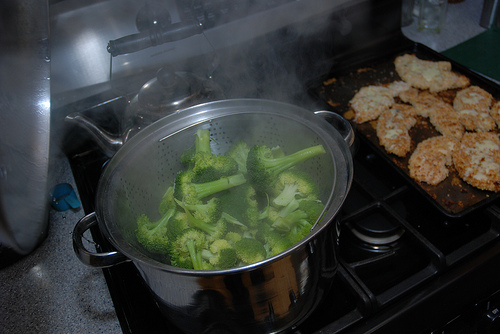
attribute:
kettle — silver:
[64, 53, 223, 155]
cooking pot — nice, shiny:
[72, 103, 359, 329]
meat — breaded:
[375, 101, 419, 158]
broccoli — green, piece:
[248, 139, 325, 184]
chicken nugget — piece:
[380, 94, 422, 176]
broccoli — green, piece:
[174, 160, 242, 214]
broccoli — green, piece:
[228, 124, 336, 199]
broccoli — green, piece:
[127, 199, 184, 256]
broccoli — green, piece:
[167, 221, 214, 269]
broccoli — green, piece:
[231, 220, 283, 272]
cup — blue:
[46, 178, 77, 210]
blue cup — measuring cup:
[39, 166, 90, 218]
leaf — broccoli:
[243, 145, 277, 193]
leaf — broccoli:
[134, 210, 166, 255]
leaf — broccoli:
[189, 147, 237, 174]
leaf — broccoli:
[231, 235, 268, 262]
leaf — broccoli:
[299, 198, 322, 217]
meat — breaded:
[409, 135, 459, 187]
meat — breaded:
[377, 103, 415, 153]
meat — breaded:
[348, 83, 393, 121]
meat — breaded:
[394, 51, 469, 93]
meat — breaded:
[456, 129, 498, 189]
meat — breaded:
[401, 89, 463, 136]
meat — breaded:
[453, 87, 497, 130]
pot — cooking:
[26, 61, 415, 332]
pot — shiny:
[142, 271, 202, 308]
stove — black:
[108, 56, 443, 327]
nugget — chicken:
[454, 130, 498, 187]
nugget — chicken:
[404, 130, 462, 185]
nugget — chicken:
[393, 50, 467, 91]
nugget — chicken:
[377, 101, 418, 158]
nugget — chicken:
[348, 80, 403, 127]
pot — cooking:
[70, 99, 355, 331]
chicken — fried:
[349, 51, 499, 188]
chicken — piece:
[409, 133, 455, 185]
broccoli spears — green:
[178, 161, 287, 241]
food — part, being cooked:
[326, 51, 498, 214]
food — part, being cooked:
[395, 96, 479, 178]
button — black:
[134, 1, 171, 36]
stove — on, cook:
[49, 0, 498, 332]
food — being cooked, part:
[396, 52, 469, 92]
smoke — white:
[92, 12, 294, 189]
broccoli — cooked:
[182, 140, 282, 244]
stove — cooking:
[47, 43, 477, 317]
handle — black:
[103, 11, 206, 57]